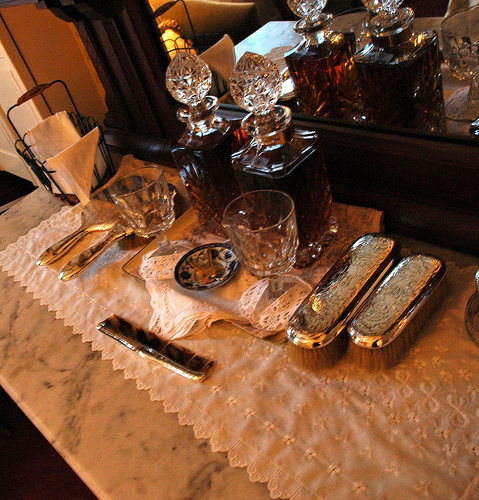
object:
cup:
[221, 187, 312, 332]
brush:
[345, 250, 446, 371]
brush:
[285, 227, 411, 372]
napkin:
[23, 109, 107, 208]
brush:
[58, 181, 188, 286]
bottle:
[350, 0, 447, 139]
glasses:
[109, 166, 199, 281]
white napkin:
[0, 154, 479, 498]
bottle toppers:
[163, 47, 223, 128]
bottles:
[166, 45, 251, 240]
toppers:
[225, 48, 290, 141]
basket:
[6, 79, 119, 204]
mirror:
[147, 0, 479, 157]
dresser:
[0, 148, 475, 498]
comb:
[94, 312, 217, 385]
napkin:
[136, 224, 316, 343]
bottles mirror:
[349, 0, 451, 132]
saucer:
[174, 241, 239, 291]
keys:
[186, 244, 228, 286]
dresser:
[221, 18, 479, 147]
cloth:
[25, 107, 99, 209]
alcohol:
[228, 128, 338, 269]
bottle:
[227, 50, 339, 269]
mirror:
[36, 169, 149, 270]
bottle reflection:
[281, 0, 358, 126]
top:
[0, 147, 479, 497]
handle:
[59, 228, 131, 284]